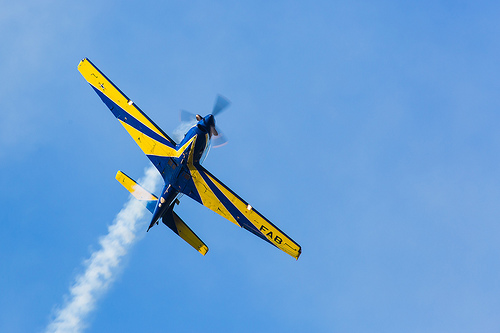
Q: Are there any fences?
A: No, there are no fences.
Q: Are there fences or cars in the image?
A: No, there are no fences or cars.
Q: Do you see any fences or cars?
A: No, there are no fences or cars.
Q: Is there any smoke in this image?
A: Yes, there is smoke.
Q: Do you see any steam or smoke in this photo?
A: Yes, there is smoke.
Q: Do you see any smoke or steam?
A: Yes, there is smoke.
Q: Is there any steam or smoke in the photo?
A: Yes, there is smoke.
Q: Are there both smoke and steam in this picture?
A: No, there is smoke but no steam.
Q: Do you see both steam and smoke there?
A: No, there is smoke but no steam.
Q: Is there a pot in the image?
A: No, there are no pots.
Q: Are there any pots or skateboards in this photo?
A: No, there are no pots or skateboards.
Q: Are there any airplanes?
A: Yes, there is an airplane.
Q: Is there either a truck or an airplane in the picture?
A: Yes, there is an airplane.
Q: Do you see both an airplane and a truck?
A: No, there is an airplane but no trucks.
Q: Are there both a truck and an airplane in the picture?
A: No, there is an airplane but no trucks.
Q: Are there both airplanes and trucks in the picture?
A: No, there is an airplane but no trucks.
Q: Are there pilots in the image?
A: No, there are no pilots.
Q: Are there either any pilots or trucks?
A: No, there are no pilots or trucks.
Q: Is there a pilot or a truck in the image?
A: No, there are no pilots or trucks.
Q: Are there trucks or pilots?
A: No, there are no pilots or trucks.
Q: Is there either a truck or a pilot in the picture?
A: No, there are no pilots or trucks.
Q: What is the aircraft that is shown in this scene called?
A: The aircraft is an airplane.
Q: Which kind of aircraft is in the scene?
A: The aircraft is an airplane.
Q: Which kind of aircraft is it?
A: The aircraft is an airplane.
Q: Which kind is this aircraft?
A: This is an airplane.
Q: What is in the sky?
A: The airplane is in the sky.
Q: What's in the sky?
A: The airplane is in the sky.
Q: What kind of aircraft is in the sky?
A: The aircraft is an airplane.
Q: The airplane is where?
A: The airplane is in the sky.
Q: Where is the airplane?
A: The airplane is in the sky.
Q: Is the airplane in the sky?
A: Yes, the airplane is in the sky.